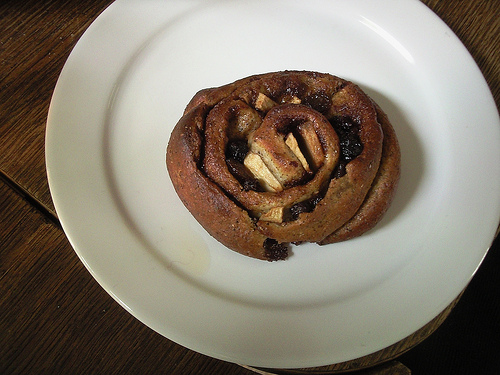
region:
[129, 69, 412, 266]
Cinamon roll on white plate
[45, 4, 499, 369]
Round white plate on table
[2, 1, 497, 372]
Table is brown wood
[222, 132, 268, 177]
Raisin on a cinamon bun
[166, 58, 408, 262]
Many swirls in the bun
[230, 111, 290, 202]
Apple chunk in cinamon roll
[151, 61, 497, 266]
Cinamon roll is brown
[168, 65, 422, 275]
Yummy looking cinamon roll on plate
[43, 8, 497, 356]
Round white plate with roll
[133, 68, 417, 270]
The roll sits on a plate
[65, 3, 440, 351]
lare white plate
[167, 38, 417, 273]
cinnomon roll on white plate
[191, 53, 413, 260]
brown breakfast pastry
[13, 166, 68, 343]
dark brown wooden table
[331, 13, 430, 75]
light reflecting on plate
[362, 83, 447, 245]
shadow cast by pastry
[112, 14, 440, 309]
one piece of pastry on white plate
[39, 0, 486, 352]
one white plate on table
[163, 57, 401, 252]
pastry in a round shape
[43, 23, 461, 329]
plain white plae with no design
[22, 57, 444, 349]
the plate is white and clean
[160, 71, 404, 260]
cinnamon bun on a plate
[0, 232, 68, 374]
small section of a wooden table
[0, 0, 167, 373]
left side of a plate on a wooden table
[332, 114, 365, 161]
gooey filling in a cinnamon roll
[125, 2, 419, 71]
small section of a white plate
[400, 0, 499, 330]
small section of a white plate on a wooden table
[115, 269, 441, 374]
small section of a white plate on a wooden table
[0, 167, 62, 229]
seam in a wooden table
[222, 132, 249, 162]
gooey filling in a cinnamon bun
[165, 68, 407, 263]
a cinnamon roll on a plate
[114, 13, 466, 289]
a raisin cinnamon roll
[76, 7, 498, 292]
a pastry with raisins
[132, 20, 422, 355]
a sweet pastry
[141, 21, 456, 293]
a pastry that is sweet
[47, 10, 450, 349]
a sweet pastry on a plate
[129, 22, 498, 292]
a pastry on a white plate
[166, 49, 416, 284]
raisins in the middle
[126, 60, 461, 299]
a cooked sweet pastry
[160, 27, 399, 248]
a cooked pastry with raisins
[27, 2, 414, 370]
a white plate on a table